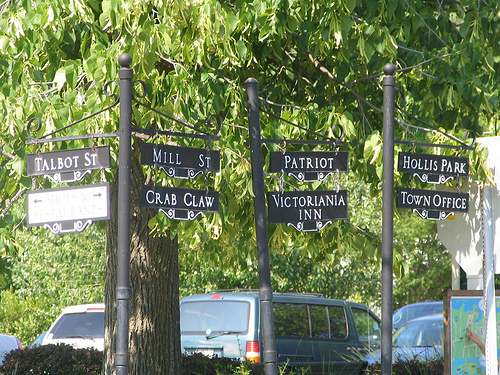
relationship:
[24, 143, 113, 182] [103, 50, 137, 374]
sign on pole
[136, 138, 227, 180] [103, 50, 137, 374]
sign on pole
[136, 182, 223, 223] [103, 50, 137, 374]
sign on pole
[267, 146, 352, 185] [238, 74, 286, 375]
sign on pole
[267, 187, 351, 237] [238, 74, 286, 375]
sign on pole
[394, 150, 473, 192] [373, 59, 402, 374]
sign on pole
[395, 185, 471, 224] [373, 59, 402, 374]
sign on pole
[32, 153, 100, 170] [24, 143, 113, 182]
writing on sign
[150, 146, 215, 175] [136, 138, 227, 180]
writing on sign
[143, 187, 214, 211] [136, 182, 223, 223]
writing on sign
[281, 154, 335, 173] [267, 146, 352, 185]
writing on sign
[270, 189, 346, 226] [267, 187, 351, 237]
writing on sign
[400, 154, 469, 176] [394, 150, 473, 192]
writing on sign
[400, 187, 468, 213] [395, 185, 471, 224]
writing on sign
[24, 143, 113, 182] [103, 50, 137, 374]
sign attached to pole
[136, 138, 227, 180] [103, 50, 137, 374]
sign attached to pole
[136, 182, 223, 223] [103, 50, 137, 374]
sign attached to pole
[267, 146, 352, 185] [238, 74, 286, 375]
sign attached to pole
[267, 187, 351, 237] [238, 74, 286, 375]
sign attached to pole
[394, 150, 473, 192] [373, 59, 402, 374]
sign attached to pole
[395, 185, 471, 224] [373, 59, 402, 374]
sign attached to pole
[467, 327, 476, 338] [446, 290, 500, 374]
finger pointing on a map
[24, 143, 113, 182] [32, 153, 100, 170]
sign reads talbot st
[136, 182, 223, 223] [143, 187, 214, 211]
sign named crab claw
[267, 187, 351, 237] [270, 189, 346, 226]
sign has writing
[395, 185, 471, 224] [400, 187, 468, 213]
sign has writing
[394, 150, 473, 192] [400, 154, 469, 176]
sign has writing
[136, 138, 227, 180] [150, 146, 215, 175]
sign has writing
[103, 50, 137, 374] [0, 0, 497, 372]
pole in front of tree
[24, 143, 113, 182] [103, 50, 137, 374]
sign hanging on pole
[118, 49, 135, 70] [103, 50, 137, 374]
top of pole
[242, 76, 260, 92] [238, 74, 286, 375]
top of pole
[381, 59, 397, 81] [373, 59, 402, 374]
top of pole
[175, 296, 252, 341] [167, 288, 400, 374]
glass of car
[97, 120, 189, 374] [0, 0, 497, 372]
trunk of tree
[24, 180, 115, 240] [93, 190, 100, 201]
sign has arrows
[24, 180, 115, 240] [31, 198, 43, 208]
sign has arrows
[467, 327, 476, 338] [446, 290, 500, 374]
finger pointing to map